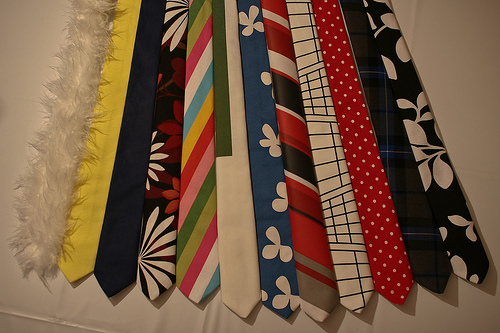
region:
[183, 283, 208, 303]
edge of a tie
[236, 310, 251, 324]
edge of a tie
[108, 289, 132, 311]
prt of a shjade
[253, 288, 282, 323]
edge of a tie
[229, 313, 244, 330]
part of a cloth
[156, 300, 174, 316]
part of a cloth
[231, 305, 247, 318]
edge of a tie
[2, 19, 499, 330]
neckties laying on white background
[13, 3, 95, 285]
white furry necktie on white background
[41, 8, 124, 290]
yellow necktie next to white fuzzy necktie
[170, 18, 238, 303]
white, blue, yellow, red, pink, and green striped necktie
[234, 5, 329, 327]
white flowers on blue necktie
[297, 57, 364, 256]
black and white necktie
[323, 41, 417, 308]
red necktie with white polka dots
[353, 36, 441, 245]
brown, black, and blue plaid necktie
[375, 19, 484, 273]
white objects on black necktie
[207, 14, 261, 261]
green block on white necktie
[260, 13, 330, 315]
the tie is stripes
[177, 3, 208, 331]
the tie is stripes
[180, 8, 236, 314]
the tie is stripes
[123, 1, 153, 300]
the tie is black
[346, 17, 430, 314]
the tie is black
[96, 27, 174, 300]
the tie is black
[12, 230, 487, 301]
rainbow of wild neckties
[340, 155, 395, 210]
red and white necktie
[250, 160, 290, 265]
blue and white necktie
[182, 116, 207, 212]
blue,yellow,red,pink,green,tie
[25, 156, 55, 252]
white fake fuzzy fur necktie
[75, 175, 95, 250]
lemon yellow silk neck tie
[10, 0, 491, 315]
assortment of crazy patterned neckties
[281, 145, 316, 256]
red,black,white,orange,gray necktie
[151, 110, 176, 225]
black white orange brown necktie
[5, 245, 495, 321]
multi colored necktie pointed ends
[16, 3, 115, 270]
white fur neck tie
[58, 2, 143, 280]
yellow cotton neck tie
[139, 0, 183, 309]
floral cotton neck tie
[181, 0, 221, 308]
striped cotton neck tie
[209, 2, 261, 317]
green and white neck tie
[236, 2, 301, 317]
blue and white neck tie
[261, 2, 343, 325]
striped silk neck tie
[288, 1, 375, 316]
black and white neck tie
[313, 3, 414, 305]
red polka dot tie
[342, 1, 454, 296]
blue plaid neck tie